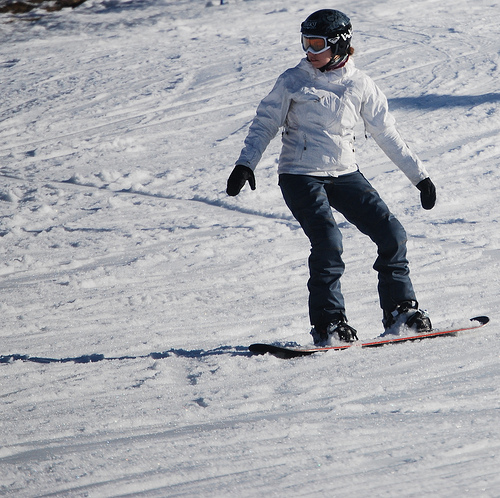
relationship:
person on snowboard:
[177, 6, 496, 392] [241, 278, 498, 363]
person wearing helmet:
[177, 6, 496, 392] [301, 6, 359, 49]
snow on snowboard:
[40, 171, 177, 370] [241, 278, 498, 363]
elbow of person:
[241, 117, 277, 147] [177, 6, 496, 392]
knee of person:
[305, 232, 348, 265] [177, 6, 496, 392]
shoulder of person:
[272, 64, 304, 100] [177, 6, 496, 392]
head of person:
[270, 5, 365, 74] [177, 6, 496, 392]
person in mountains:
[177, 6, 496, 392] [4, 1, 497, 485]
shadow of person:
[3, 319, 235, 398] [177, 6, 496, 392]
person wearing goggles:
[177, 6, 496, 392] [299, 30, 326, 55]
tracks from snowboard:
[36, 102, 229, 151] [241, 278, 498, 363]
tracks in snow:
[36, 102, 229, 151] [40, 171, 177, 370]